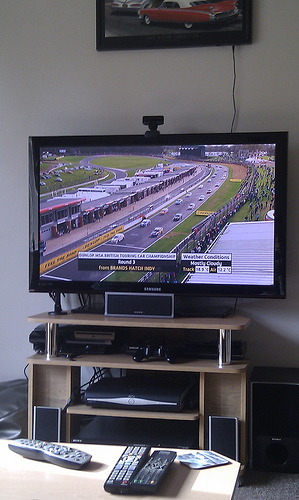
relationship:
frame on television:
[28, 133, 288, 296] [27, 115, 288, 301]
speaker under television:
[103, 290, 177, 318] [27, 115, 288, 301]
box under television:
[85, 377, 192, 410] [27, 115, 288, 301]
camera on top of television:
[143, 114, 164, 136] [27, 115, 288, 301]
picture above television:
[103, 0, 243, 34] [27, 115, 288, 301]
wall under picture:
[0, 1, 298, 383] [103, 0, 243, 34]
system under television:
[30, 328, 126, 358] [27, 115, 288, 301]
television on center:
[27, 115, 288, 301] [26, 312, 252, 487]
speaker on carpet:
[249, 369, 298, 477] [234, 468, 298, 499]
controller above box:
[134, 348, 150, 363] [85, 377, 192, 410]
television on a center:
[27, 115, 288, 301] [26, 312, 252, 487]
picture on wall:
[103, 0, 243, 34] [0, 1, 298, 383]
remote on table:
[8, 437, 91, 471] [0, 438, 246, 499]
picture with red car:
[103, 0, 243, 34] [136, 3, 238, 28]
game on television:
[40, 144, 276, 285] [27, 115, 288, 301]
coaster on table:
[178, 449, 230, 471] [0, 438, 246, 499]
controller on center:
[134, 348, 150, 363] [26, 312, 252, 487]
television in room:
[27, 115, 288, 301] [0, 1, 298, 499]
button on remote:
[65, 446, 73, 453] [8, 437, 91, 471]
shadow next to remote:
[85, 460, 108, 474] [8, 437, 91, 471]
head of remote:
[49, 439, 93, 470] [8, 437, 91, 471]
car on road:
[171, 212, 182, 224] [41, 163, 228, 281]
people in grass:
[37, 159, 100, 187] [40, 155, 165, 202]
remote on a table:
[8, 437, 91, 471] [0, 438, 246, 499]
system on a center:
[30, 328, 126, 358] [26, 312, 252, 487]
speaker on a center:
[103, 290, 177, 318] [26, 312, 252, 487]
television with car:
[27, 115, 288, 301] [171, 212, 182, 224]